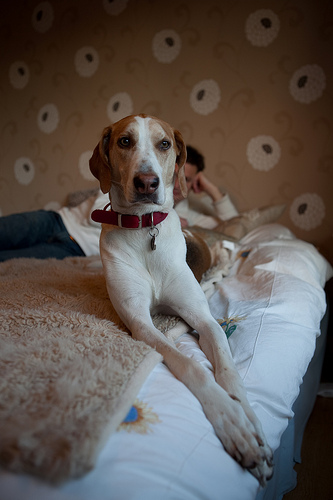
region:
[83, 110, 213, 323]
A dog laying on a bed.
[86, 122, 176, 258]
A dog wearing a red collar.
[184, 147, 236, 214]
A person laying behind the dog.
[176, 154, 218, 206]
A person resting with his fist to head.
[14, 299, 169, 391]
A carpet lays on top of the bed.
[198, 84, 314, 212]
A tan and white wall behind the bed.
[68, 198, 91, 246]
A person wearing a white shirt.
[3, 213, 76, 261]
A person wearing blue jeans.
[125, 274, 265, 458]
A dog with white legs laying on top of bed.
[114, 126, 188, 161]
A dog with tan fur surrounding his eyes.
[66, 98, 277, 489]
dog with a red collar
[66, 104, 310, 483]
dog laying on a bed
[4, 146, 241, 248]
man laying on a bed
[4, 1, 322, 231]
wall with floral wallpaper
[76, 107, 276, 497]
white and brown dog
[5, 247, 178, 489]
light brown carpet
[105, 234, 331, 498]
white comforter on bed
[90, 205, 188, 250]
dark red dog collar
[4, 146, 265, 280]
man wearing blue jeans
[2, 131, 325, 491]
man and dog on bed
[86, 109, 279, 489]
Dog on the bed.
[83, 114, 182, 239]
Red collar on the dog.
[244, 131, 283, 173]
Lamb on the wall paper.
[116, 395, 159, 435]
flower design on the blanket.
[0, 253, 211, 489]
Brown blanket on the bed.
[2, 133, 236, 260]
Man laying on the bed.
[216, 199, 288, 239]
Brown pillow on the bed.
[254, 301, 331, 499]
Gray bed skirt on the bed.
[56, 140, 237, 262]
Man is wearing white shirt.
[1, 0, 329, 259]
Wall paper on the wall.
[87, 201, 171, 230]
the red collar attached to the dog's neck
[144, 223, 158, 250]
the tag on the collar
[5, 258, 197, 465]
the pillow the dog is laying on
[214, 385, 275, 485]
the paws hanging on the edge of the bed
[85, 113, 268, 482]
a relaxed dog laying on the bed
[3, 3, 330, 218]
the wallpaper with flowers on it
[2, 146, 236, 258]
a man laying on the bed with the dog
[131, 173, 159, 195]
the colorful nose on the dog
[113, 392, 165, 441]
the flower on the comforter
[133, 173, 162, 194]
the colorful nose of the dog